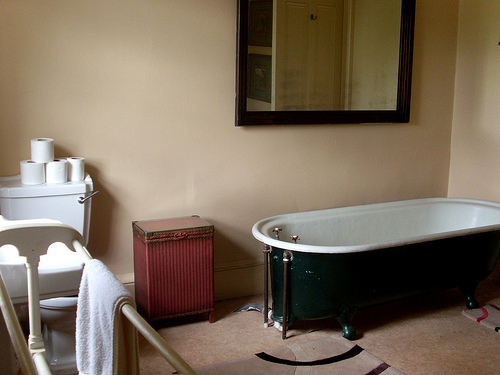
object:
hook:
[308, 7, 318, 22]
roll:
[67, 158, 90, 182]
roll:
[43, 159, 69, 185]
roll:
[29, 137, 58, 160]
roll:
[20, 160, 44, 185]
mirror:
[233, 1, 419, 129]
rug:
[176, 329, 404, 372]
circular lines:
[257, 342, 363, 367]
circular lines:
[468, 302, 499, 335]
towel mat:
[171, 323, 405, 373]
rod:
[70, 222, 192, 368]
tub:
[240, 185, 498, 332]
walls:
[3, 0, 499, 279]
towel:
[73, 262, 133, 373]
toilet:
[2, 172, 98, 368]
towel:
[466, 298, 498, 330]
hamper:
[130, 215, 226, 327]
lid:
[129, 217, 221, 244]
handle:
[76, 189, 101, 204]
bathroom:
[2, 4, 496, 374]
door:
[272, 2, 344, 109]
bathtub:
[255, 196, 499, 323]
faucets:
[270, 224, 300, 246]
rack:
[0, 222, 196, 374]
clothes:
[69, 254, 136, 374]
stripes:
[257, 342, 391, 369]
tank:
[1, 178, 94, 303]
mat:
[223, 323, 397, 373]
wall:
[0, 0, 499, 283]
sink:
[1, 216, 93, 305]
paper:
[18, 125, 90, 185]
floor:
[120, 289, 499, 373]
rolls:
[15, 137, 87, 184]